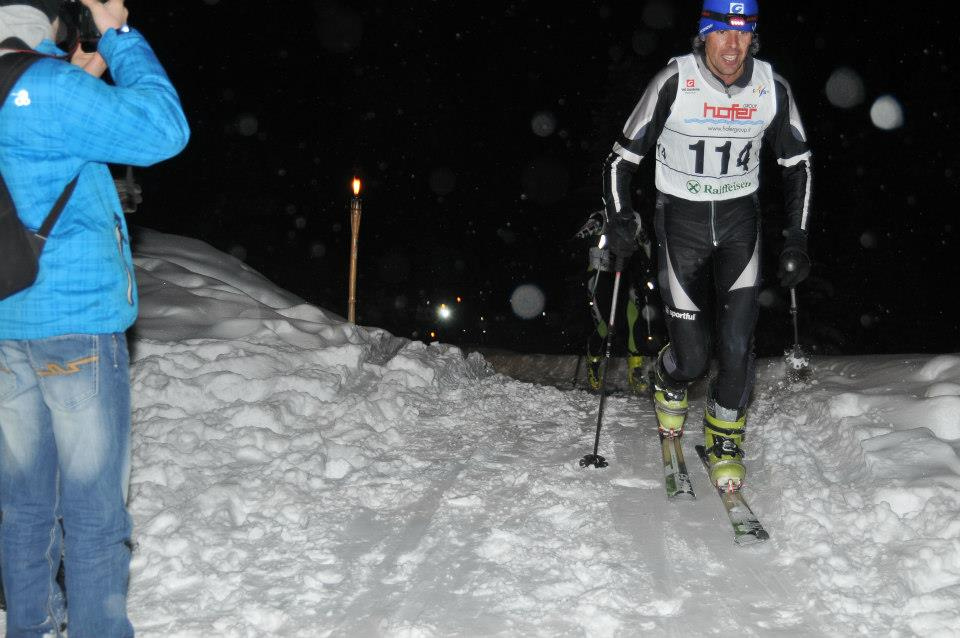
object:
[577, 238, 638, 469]
pole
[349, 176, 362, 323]
lamp post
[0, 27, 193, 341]
jacket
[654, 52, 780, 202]
jersey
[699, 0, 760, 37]
hat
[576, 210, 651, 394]
person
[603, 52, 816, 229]
jacket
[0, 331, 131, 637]
jeans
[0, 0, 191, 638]
person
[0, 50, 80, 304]
backpack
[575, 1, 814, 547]
man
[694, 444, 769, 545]
ski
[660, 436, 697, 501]
ski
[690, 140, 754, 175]
number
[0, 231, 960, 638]
snow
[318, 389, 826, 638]
track